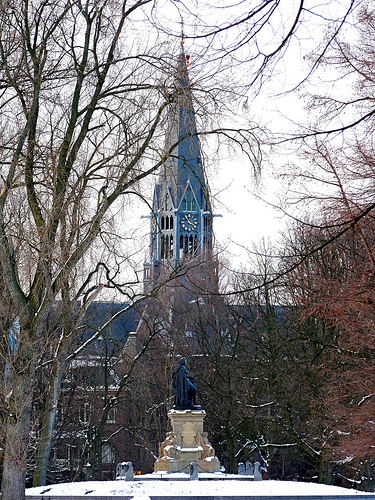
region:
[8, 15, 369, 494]
an important building with a clock tower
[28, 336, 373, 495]
a statue is in front of the building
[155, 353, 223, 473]
the statue is sitting on a stone pedestal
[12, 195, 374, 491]
snow has fallen on the statue and the trees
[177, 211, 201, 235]
the clock has a dark face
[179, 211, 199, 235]
the clock's hands and roman numerals are gold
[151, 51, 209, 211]
the tower's cupola is gray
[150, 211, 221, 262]
open arched windows are on the tower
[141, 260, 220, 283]
columns are around the base of the tower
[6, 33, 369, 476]
the trees are nearly bare of leaves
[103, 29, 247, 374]
a church tower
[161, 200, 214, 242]
a clock on a church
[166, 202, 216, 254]
a church clock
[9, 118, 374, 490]
a church building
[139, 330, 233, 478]
a statue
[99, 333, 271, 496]
a statue with a chain around it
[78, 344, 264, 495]
a statue in the snow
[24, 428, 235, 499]
the ground cover in snow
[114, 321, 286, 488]
a statue standing tall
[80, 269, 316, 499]
a statue in front of the church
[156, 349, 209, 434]
A large gray statue.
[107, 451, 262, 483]
A barrier around the fountain.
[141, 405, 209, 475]
Water fountain that is not on.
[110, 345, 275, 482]
Water fountain with statue on it.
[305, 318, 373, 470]
Trees with an orange shade to it.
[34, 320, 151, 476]
Large building made of bricks.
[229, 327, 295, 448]
Green tree with snow on limbs.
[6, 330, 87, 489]
Trees with no leaves.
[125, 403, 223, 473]
Statues built into fountain base.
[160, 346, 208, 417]
Gray statue with a cape.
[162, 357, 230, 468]
statue in the middle of town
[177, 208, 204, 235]
clock on large church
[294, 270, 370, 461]
tree with orange leaves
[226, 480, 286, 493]
white snow on top of roof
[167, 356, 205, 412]
black statue on top of building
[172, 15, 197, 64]
steeple on top of church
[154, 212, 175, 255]
openings of arches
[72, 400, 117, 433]
windows of church in background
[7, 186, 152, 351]
tree with no leaves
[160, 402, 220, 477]
tan base of statue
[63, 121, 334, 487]
wintry day in front of the clock tower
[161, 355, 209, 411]
statue appears to be dark blue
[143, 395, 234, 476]
statue is on beige pedestal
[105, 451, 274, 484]
protective barrier around statue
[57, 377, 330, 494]
snow on ground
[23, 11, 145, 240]
trees have no leaves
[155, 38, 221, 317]
clock tower in background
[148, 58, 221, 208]
clock tower has blue roof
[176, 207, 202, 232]
clock numbers are gold in color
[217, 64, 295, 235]
sky is white with clouds